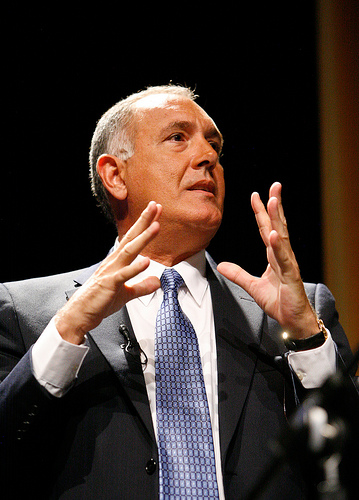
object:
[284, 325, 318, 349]
watch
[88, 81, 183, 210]
hair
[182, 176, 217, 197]
mouth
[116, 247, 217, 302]
collar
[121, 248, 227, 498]
white shirt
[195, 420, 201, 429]
squares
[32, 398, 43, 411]
button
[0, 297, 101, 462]
man's arm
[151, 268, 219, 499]
blue tie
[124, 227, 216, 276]
neck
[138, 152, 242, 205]
ground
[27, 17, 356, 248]
screen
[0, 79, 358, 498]
man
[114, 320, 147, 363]
mic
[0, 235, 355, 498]
coat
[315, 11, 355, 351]
wall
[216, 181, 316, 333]
hand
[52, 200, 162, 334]
hand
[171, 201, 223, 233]
chin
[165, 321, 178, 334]
squares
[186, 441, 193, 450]
squares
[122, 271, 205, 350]
knot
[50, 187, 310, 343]
gesture